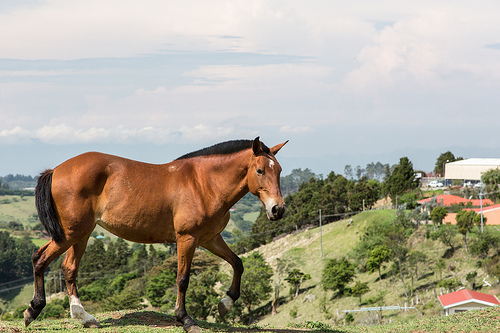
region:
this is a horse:
[10, 135, 292, 328]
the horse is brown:
[21, 123, 311, 330]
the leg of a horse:
[20, 193, 74, 322]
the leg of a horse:
[39, 205, 96, 330]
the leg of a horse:
[163, 202, 203, 329]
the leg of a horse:
[210, 233, 240, 328]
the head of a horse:
[241, 120, 299, 237]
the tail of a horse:
[27, 165, 72, 253]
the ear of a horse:
[246, 133, 268, 165]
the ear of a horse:
[259, 134, 297, 161]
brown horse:
[41, 137, 288, 323]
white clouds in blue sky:
[11, 14, 83, 67]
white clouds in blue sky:
[17, 52, 90, 99]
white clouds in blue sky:
[12, 106, 76, 130]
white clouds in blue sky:
[80, 7, 155, 55]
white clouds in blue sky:
[59, 40, 183, 103]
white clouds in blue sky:
[188, 14, 290, 73]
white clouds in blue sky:
[181, 68, 276, 109]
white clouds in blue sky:
[322, 2, 493, 74]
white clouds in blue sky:
[299, 73, 425, 118]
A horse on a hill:
[17, 131, 307, 332]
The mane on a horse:
[173, 138, 267, 164]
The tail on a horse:
[25, 166, 72, 246]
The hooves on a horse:
[17, 289, 247, 330]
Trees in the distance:
[274, 158, 436, 228]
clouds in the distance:
[8, 103, 297, 157]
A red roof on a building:
[435, 281, 499, 307]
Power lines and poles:
[14, 256, 103, 296]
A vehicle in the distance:
[426, 178, 445, 190]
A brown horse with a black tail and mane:
[17, 126, 302, 332]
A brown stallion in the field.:
[43, 138, 305, 295]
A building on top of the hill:
[438, 142, 478, 209]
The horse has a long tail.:
[28, 160, 63, 242]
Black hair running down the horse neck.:
[180, 135, 252, 161]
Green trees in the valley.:
[285, 165, 415, 225]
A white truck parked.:
[425, 167, 441, 197]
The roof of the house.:
[426, 285, 494, 305]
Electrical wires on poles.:
[305, 190, 381, 216]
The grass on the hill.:
[283, 234, 335, 287]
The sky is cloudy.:
[71, 36, 400, 140]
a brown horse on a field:
[16, 127, 298, 332]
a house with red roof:
[431, 284, 498, 322]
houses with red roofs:
[401, 183, 499, 234]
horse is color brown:
[13, 127, 300, 332]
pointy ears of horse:
[239, 133, 297, 165]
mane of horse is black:
[168, 129, 264, 160]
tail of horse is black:
[27, 163, 69, 253]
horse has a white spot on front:
[258, 145, 290, 222]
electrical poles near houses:
[249, 193, 488, 238]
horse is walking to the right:
[13, 122, 298, 327]